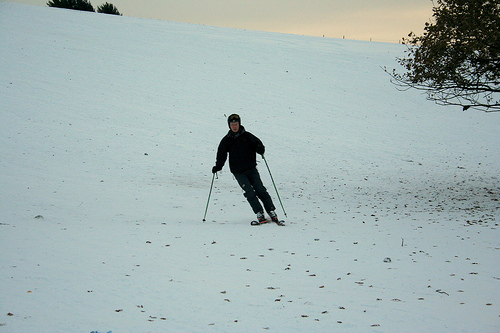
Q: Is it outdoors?
A: Yes, it is outdoors.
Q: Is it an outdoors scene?
A: Yes, it is outdoors.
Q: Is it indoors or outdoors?
A: It is outdoors.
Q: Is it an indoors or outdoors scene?
A: It is outdoors.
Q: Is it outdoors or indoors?
A: It is outdoors.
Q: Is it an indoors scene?
A: No, it is outdoors.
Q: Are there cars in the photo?
A: No, there are no cars.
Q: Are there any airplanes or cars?
A: No, there are no cars or airplanes.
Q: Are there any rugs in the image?
A: No, there are no rugs.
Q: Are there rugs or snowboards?
A: No, there are no rugs or snowboards.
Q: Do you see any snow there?
A: Yes, there is snow.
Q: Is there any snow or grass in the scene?
A: Yes, there is snow.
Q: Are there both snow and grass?
A: No, there is snow but no grass.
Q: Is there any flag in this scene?
A: No, there are no flags.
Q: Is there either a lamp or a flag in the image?
A: No, there are no flags or lamps.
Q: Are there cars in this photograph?
A: No, there are no cars.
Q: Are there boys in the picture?
A: No, there are no boys.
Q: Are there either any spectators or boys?
A: No, there are no boys or spectators.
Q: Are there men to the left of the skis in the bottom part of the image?
A: Yes, there is a man to the left of the skis.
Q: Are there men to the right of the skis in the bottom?
A: No, the man is to the left of the skis.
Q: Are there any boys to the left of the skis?
A: No, there is a man to the left of the skis.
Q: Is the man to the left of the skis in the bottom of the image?
A: Yes, the man is to the left of the skis.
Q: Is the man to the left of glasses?
A: No, the man is to the left of the skis.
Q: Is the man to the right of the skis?
A: No, the man is to the left of the skis.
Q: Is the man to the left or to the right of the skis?
A: The man is to the left of the skis.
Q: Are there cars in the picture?
A: No, there are no cars.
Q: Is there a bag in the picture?
A: No, there are no bags.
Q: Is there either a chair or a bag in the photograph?
A: No, there are no bags or chairs.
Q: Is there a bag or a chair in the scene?
A: No, there are no bags or chairs.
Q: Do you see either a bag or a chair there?
A: No, there are no bags or chairs.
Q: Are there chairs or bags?
A: No, there are no bags or chairs.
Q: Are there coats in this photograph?
A: Yes, there is a coat.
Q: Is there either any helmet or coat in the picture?
A: Yes, there is a coat.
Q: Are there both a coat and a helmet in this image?
A: Yes, there are both a coat and a helmet.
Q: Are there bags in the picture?
A: No, there are no bags.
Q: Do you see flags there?
A: No, there are no flags.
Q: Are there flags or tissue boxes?
A: No, there are no flags or tissue boxes.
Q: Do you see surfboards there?
A: No, there are no surfboards.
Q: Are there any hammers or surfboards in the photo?
A: No, there are no surfboards or hammers.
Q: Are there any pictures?
A: No, there are no pictures.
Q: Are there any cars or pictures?
A: No, there are no pictures or cars.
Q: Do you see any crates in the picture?
A: No, there are no crates.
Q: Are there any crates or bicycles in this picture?
A: No, there are no crates or bicycles.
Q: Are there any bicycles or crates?
A: No, there are no crates or bicycles.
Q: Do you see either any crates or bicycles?
A: No, there are no crates or bicycles.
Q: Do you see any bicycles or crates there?
A: No, there are no crates or bicycles.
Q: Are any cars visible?
A: No, there are no cars.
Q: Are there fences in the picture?
A: Yes, there is a fence.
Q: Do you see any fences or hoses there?
A: Yes, there is a fence.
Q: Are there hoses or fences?
A: Yes, there is a fence.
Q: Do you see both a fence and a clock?
A: No, there is a fence but no clocks.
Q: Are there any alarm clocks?
A: No, there are no alarm clocks.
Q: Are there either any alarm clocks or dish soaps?
A: No, there are no alarm clocks or dish soaps.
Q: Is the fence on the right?
A: Yes, the fence is on the right of the image.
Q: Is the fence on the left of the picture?
A: No, the fence is on the right of the image.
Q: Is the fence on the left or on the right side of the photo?
A: The fence is on the right of the image.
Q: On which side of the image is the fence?
A: The fence is on the right of the image.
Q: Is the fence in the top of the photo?
A: Yes, the fence is in the top of the image.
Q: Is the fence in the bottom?
A: No, the fence is in the top of the image.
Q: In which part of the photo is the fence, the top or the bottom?
A: The fence is in the top of the image.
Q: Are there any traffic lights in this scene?
A: No, there are no traffic lights.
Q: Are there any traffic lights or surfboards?
A: No, there are no traffic lights or surfboards.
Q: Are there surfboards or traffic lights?
A: No, there are no traffic lights or surfboards.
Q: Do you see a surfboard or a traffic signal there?
A: No, there are no traffic lights or surfboards.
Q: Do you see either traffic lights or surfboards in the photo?
A: No, there are no traffic lights or surfboards.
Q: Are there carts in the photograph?
A: No, there are no carts.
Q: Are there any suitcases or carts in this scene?
A: No, there are no carts or suitcases.